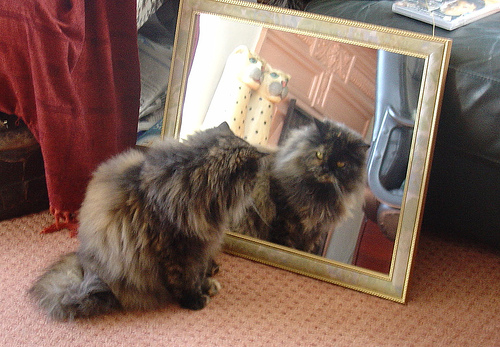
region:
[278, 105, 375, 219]
The cats reflection in the mirror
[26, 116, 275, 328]
A fluffy cat looking at reflection in the mirror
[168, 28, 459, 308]
A mirror leaning against a couch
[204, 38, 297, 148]
A cat statue reflected in a mirror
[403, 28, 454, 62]
Part of the frame around a mirror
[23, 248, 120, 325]
The tail of the cat looking in the mirror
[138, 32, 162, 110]
Part of a newspaper beside the mirror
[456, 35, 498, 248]
Part of the couch the mirror is leaning against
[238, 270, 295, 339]
The carpet in the room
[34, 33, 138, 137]
Part of a red curtain or blanket behind the cat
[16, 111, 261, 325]
fluffy cat sitting down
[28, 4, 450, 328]
cat looking in a mirror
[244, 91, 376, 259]
reflection of the cat in the mirror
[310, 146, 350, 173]
two bright green eyes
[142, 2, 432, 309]
gold frame around the mirror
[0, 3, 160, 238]
red fabric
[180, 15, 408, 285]
reflection in the mirror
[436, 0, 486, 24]
picture of a face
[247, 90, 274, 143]
black polka dots on a yellow background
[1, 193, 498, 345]
carpet on the floor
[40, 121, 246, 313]
A brown fuzzy cat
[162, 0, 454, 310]
A square mirror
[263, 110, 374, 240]
Cats reflection in the mirror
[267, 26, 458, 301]
Gold frame around mirror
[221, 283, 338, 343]
Pink carpeted floor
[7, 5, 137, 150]
Long burgundy curtain touching floor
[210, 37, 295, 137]
Reflection of two cat figurines in mirror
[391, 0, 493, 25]
Photo in a frame behind mirror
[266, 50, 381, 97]
Pink mantel reflection in mirror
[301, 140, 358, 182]
Reflection of cat with green eyes in mirror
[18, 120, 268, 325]
A fuzzy cat in front of a mirror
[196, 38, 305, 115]
polk dotted cats in a morrow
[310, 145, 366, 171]
eyes of a fuzzy cat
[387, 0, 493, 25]
a cd on the chair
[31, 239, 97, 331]
a fuzzy cats tail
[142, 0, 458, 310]
A mirror on the floor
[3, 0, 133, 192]
a throw in the corner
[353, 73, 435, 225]
A back of a chair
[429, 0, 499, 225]
A leather chair behind the mirror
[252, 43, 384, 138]
a fireplace in the mirror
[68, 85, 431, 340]
a cat looking in a mirror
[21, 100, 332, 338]
a fluffy cat in front of a mirror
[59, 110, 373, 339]
a cat staring into a mirror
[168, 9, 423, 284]
a mirror with a nice frame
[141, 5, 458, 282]
a mirror reflecting a cat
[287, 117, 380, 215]
the reflection of a fluffy grey cat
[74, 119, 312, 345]
a grey cat on the spotted pink carpet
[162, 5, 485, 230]
a mirror leaning against a leather sofa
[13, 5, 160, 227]
a red blanket draped over something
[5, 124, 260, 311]
a cat with a bushy tail